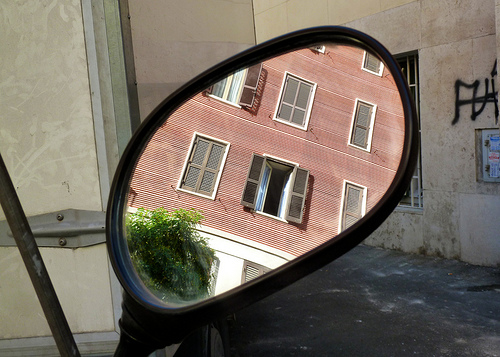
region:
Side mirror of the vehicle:
[78, 7, 443, 307]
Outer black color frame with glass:
[79, 10, 422, 355]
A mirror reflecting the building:
[121, 47, 408, 271]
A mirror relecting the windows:
[188, 42, 390, 234]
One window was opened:
[235, 144, 315, 239]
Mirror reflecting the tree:
[131, 210, 218, 287]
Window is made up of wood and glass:
[191, 126, 356, 221]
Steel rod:
[8, 150, 68, 337]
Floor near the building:
[287, 228, 493, 338]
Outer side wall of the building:
[415, 7, 499, 251]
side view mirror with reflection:
[103, 22, 418, 319]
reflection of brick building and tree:
[136, 45, 406, 315]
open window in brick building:
[237, 149, 312, 225]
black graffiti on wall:
[450, 60, 499, 122]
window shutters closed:
[176, 129, 232, 201]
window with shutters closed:
[271, 65, 316, 125]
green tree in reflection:
[127, 202, 217, 296]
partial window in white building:
[400, 46, 427, 212]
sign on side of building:
[472, 123, 499, 183]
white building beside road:
[403, 40, 499, 268]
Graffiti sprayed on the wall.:
[437, 46, 497, 124]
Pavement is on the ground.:
[311, 290, 458, 345]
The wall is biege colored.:
[386, 11, 481, 34]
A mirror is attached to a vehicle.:
[65, 5, 443, 340]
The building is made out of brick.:
[277, 136, 332, 151]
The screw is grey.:
[45, 210, 75, 220]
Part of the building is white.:
[211, 236, 237, 251]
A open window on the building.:
[230, 137, 315, 227]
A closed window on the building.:
[171, 125, 231, 213]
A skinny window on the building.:
[340, 87, 382, 154]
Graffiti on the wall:
[450, 62, 498, 113]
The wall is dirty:
[393, 204, 480, 273]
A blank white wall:
[2, 46, 77, 188]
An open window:
[247, 154, 315, 222]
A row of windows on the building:
[214, 57, 379, 159]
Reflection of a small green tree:
[132, 208, 210, 291]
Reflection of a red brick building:
[171, 70, 353, 222]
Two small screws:
[55, 211, 81, 245]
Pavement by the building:
[310, 269, 455, 346]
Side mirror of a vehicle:
[87, 36, 450, 313]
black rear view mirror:
[91, 30, 402, 325]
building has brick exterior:
[172, 82, 431, 204]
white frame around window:
[155, 140, 230, 207]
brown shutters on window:
[238, 151, 308, 228]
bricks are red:
[219, 108, 283, 150]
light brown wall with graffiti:
[430, 18, 499, 235]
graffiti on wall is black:
[427, 34, 499, 126]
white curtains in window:
[212, 63, 243, 119]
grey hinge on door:
[2, 190, 127, 272]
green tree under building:
[150, 221, 242, 306]